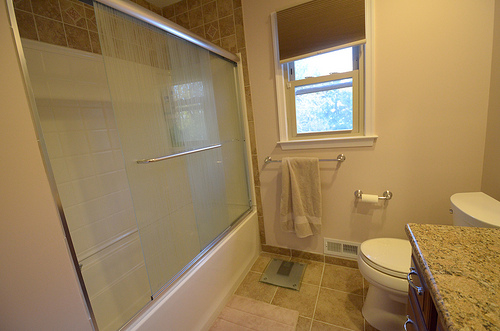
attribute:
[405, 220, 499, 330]
countertop — granite, marble, brown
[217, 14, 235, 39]
tile — brown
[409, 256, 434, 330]
drawer — wooden, dark brown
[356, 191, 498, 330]
toilet — white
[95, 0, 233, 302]
door — glass, clear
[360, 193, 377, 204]
toilet paper — white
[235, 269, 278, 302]
tile — brown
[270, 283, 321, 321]
tile — brown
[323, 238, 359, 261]
vent — white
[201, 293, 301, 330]
rug — cream colored, pink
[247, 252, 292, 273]
tile — brown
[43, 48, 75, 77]
tile — white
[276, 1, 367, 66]
blind — tan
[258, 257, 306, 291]
scale — clear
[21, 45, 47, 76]
tile — white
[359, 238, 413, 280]
toilet seat — down